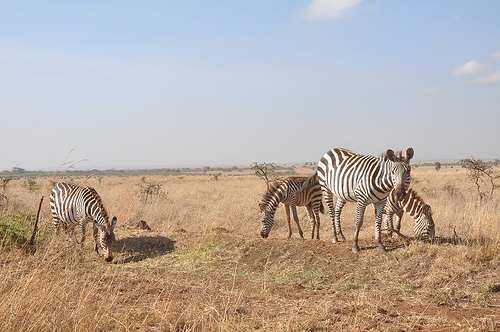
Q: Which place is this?
A: It is a field.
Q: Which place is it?
A: It is a field.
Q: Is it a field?
A: Yes, it is a field.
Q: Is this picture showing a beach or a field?
A: It is showing a field.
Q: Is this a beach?
A: No, it is a field.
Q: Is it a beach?
A: No, it is a field.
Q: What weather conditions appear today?
A: It is clear.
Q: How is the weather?
A: It is clear.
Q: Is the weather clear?
A: Yes, it is clear.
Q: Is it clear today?
A: Yes, it is clear.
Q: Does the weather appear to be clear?
A: Yes, it is clear.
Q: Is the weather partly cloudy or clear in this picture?
A: It is clear.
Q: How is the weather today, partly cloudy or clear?
A: It is clear.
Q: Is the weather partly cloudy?
A: No, it is clear.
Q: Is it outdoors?
A: Yes, it is outdoors.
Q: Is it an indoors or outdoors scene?
A: It is outdoors.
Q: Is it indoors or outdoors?
A: It is outdoors.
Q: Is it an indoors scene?
A: No, it is outdoors.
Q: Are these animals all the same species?
A: Yes, all the animals are zebras.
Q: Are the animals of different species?
A: No, all the animals are zebras.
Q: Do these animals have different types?
A: No, all the animals are zebras.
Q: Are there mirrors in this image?
A: No, there are no mirrors.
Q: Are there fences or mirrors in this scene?
A: No, there are no mirrors or fences.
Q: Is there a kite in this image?
A: No, there are no kites.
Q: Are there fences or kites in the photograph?
A: No, there are no kites or fences.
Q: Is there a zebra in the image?
A: Yes, there is a zebra.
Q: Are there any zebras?
A: Yes, there is a zebra.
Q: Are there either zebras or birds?
A: Yes, there is a zebra.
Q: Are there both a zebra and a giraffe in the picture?
A: No, there is a zebra but no giraffes.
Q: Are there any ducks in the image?
A: No, there are no ducks.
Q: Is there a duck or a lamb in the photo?
A: No, there are no ducks or lambs.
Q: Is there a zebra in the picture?
A: Yes, there are zebras.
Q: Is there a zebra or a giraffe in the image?
A: Yes, there are zebras.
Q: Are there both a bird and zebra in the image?
A: No, there are zebras but no birds.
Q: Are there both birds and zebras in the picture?
A: No, there are zebras but no birds.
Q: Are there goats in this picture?
A: No, there are no goats.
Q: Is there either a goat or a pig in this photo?
A: No, there are no goats or pigs.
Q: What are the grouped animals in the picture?
A: The animals are zebras.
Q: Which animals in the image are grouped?
A: The animals are zebras.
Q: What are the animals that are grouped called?
A: The animals are zebras.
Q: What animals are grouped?
A: The animals are zebras.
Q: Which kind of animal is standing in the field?
A: The animals are zebras.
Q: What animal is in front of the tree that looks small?
A: The zebras are in front of the tree.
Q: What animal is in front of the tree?
A: The zebras are in front of the tree.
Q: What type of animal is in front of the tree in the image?
A: The animals are zebras.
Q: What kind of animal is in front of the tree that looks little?
A: The animals are zebras.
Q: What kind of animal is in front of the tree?
A: The animals are zebras.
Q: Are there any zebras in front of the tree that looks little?
A: Yes, there are zebras in front of the tree.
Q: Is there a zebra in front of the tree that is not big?
A: Yes, there are zebras in front of the tree.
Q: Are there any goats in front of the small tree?
A: No, there are zebras in front of the tree.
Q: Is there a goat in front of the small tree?
A: No, there are zebras in front of the tree.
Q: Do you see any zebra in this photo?
A: Yes, there is a zebra.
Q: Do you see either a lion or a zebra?
A: Yes, there is a zebra.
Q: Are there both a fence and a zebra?
A: No, there is a zebra but no fences.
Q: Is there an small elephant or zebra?
A: Yes, there is a small zebra.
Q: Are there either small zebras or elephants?
A: Yes, there is a small zebra.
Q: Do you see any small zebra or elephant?
A: Yes, there is a small zebra.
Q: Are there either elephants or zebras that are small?
A: Yes, the zebra is small.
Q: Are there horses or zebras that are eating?
A: Yes, the zebra is eating.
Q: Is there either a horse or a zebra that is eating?
A: Yes, the zebra is eating.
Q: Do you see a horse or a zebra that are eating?
A: Yes, the zebra is eating.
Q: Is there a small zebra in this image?
A: Yes, there is a small zebra.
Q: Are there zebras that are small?
A: Yes, there is a zebra that is small.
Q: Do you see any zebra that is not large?
A: Yes, there is a small zebra.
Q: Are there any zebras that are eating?
A: Yes, there is a zebra that is eating.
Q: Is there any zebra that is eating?
A: Yes, there is a zebra that is eating.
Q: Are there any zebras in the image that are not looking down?
A: Yes, there is a zebra that is eating.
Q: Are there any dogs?
A: No, there are no dogs.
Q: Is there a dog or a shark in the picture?
A: No, there are no dogs or sharks.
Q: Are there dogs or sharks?
A: No, there are no dogs or sharks.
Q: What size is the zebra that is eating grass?
A: The zebra is small.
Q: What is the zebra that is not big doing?
A: The zebra is eating.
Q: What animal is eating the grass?
A: The zebra is eating the grass.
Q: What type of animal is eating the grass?
A: The animal is a zebra.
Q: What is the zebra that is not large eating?
A: The zebra is eating grass.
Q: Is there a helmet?
A: No, there are no helmets.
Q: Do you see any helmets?
A: No, there are no helmets.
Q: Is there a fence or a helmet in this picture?
A: No, there are no helmets or fences.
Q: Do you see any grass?
A: Yes, there is grass.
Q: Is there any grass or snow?
A: Yes, there is grass.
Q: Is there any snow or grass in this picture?
A: Yes, there is grass.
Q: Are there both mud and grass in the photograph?
A: No, there is grass but no mud.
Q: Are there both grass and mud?
A: No, there is grass but no mud.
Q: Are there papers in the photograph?
A: No, there are no papers.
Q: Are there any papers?
A: No, there are no papers.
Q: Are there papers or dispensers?
A: No, there are no papers or dispensers.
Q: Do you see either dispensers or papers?
A: No, there are no papers or dispensers.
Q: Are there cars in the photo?
A: No, there are no cars.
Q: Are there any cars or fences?
A: No, there are no cars or fences.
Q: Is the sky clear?
A: Yes, the sky is clear.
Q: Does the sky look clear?
A: Yes, the sky is clear.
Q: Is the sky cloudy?
A: No, the sky is clear.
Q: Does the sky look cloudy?
A: No, the sky is clear.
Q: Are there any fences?
A: No, there are no fences.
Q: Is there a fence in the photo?
A: No, there are no fences.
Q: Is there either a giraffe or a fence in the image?
A: No, there are no fences or giraffes.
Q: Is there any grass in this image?
A: Yes, there is grass.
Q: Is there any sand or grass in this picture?
A: Yes, there is grass.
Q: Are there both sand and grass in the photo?
A: No, there is grass but no sand.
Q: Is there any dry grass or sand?
A: Yes, there is dry grass.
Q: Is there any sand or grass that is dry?
A: Yes, the grass is dry.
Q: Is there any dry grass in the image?
A: Yes, there is dry grass.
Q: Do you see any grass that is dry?
A: Yes, there is dry grass.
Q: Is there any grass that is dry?
A: Yes, there is grass that is dry.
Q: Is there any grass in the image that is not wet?
A: Yes, there is dry grass.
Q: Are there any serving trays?
A: No, there are no serving trays.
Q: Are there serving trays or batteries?
A: No, there are no serving trays or batteries.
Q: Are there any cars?
A: No, there are no cars.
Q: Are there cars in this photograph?
A: No, there are no cars.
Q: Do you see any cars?
A: No, there are no cars.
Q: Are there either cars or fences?
A: No, there are no cars or fences.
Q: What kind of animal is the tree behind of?
A: The tree is behind the zebras.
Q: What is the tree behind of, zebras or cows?
A: The tree is behind zebras.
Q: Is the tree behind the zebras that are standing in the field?
A: Yes, the tree is behind the zebras.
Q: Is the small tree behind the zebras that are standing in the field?
A: Yes, the tree is behind the zebras.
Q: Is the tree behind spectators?
A: No, the tree is behind the zebras.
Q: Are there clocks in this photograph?
A: No, there are no clocks.